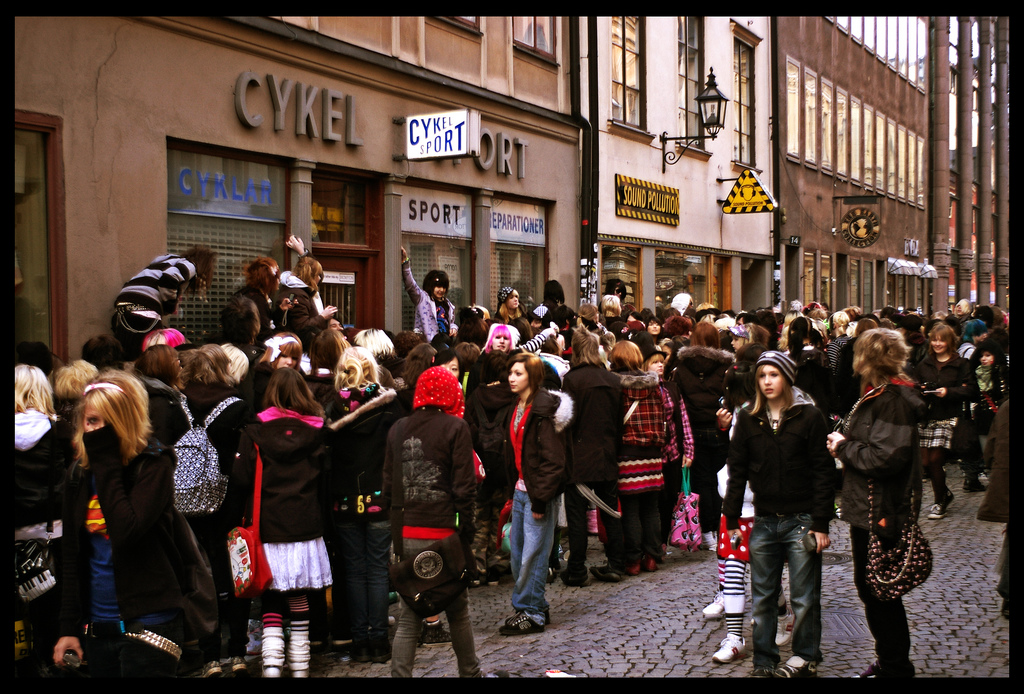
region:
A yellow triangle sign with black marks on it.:
[715, 163, 779, 217]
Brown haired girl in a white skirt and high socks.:
[228, 365, 334, 676]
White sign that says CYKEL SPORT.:
[402, 106, 482, 160]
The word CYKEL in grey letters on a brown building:
[234, 65, 367, 151]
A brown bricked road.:
[327, 468, 1008, 681]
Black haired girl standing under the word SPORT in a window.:
[393, 244, 460, 349]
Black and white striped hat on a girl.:
[750, 345, 801, 391]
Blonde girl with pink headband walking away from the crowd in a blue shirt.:
[45, 372, 213, 679]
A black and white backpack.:
[168, 380, 246, 513]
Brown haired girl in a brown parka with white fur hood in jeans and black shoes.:
[493, 353, 576, 639]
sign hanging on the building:
[836, 195, 893, 257]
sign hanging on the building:
[391, 97, 491, 174]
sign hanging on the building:
[609, 168, 695, 230]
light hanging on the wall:
[661, 57, 739, 168]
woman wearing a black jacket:
[391, 414, 469, 517]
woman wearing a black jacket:
[727, 404, 826, 509]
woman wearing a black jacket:
[830, 372, 923, 518]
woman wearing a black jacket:
[47, 432, 204, 639]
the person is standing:
[220, 373, 347, 671]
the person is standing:
[83, 382, 175, 674]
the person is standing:
[750, 351, 802, 655]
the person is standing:
[807, 307, 928, 659]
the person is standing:
[595, 350, 690, 554]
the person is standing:
[675, 310, 737, 358]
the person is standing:
[469, 290, 567, 351]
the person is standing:
[400, 256, 478, 390]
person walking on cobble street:
[495, 351, 569, 639]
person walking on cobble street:
[826, 324, 929, 677]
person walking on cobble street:
[381, 369, 498, 684]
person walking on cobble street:
[320, 344, 403, 665]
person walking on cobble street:
[230, 362, 344, 683]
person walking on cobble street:
[54, 367, 202, 682]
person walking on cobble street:
[606, 333, 684, 576]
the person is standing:
[263, 408, 325, 661]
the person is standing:
[718, 326, 835, 655]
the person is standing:
[80, 372, 161, 592]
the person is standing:
[456, 285, 537, 551]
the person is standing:
[490, 306, 566, 390]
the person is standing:
[136, 361, 285, 565]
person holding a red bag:
[222, 364, 337, 682]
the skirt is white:
[258, 537, 332, 589]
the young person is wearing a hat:
[721, 351, 840, 690]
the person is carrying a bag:
[830, 322, 933, 684]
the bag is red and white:
[225, 436, 276, 596]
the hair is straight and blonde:
[73, 366, 151, 469]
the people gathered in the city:
[13, 12, 1012, 679]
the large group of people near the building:
[11, 12, 1014, 680]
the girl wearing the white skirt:
[223, 366, 334, 681]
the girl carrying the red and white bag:
[229, 367, 331, 674]